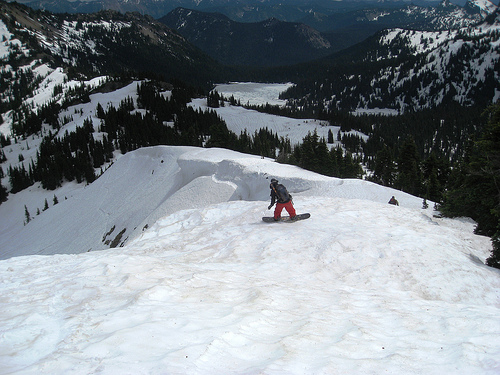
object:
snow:
[0, 146, 500, 375]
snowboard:
[256, 213, 313, 223]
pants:
[272, 199, 299, 220]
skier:
[262, 177, 299, 220]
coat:
[266, 182, 294, 207]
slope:
[0, 147, 183, 253]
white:
[213, 77, 302, 111]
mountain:
[158, 4, 375, 76]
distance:
[194, 0, 469, 20]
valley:
[195, 88, 369, 152]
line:
[127, 78, 182, 124]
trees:
[1, 14, 95, 122]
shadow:
[265, 222, 309, 227]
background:
[150, 8, 414, 65]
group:
[351, 31, 420, 58]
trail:
[127, 278, 180, 309]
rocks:
[102, 218, 138, 250]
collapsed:
[208, 347, 261, 372]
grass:
[161, 157, 167, 165]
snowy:
[53, 79, 153, 120]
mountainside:
[11, 2, 247, 106]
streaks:
[424, 260, 482, 281]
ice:
[214, 79, 267, 97]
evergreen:
[270, 127, 488, 178]